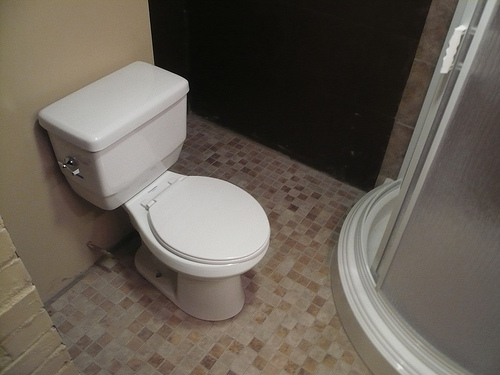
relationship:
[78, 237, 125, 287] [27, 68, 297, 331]
brown pipes on toilet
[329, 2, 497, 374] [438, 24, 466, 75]
shower door on towel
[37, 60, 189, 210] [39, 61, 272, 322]
water tank on toilet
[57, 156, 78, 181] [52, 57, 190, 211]
handle on tank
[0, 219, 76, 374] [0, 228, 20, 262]
wall of brick